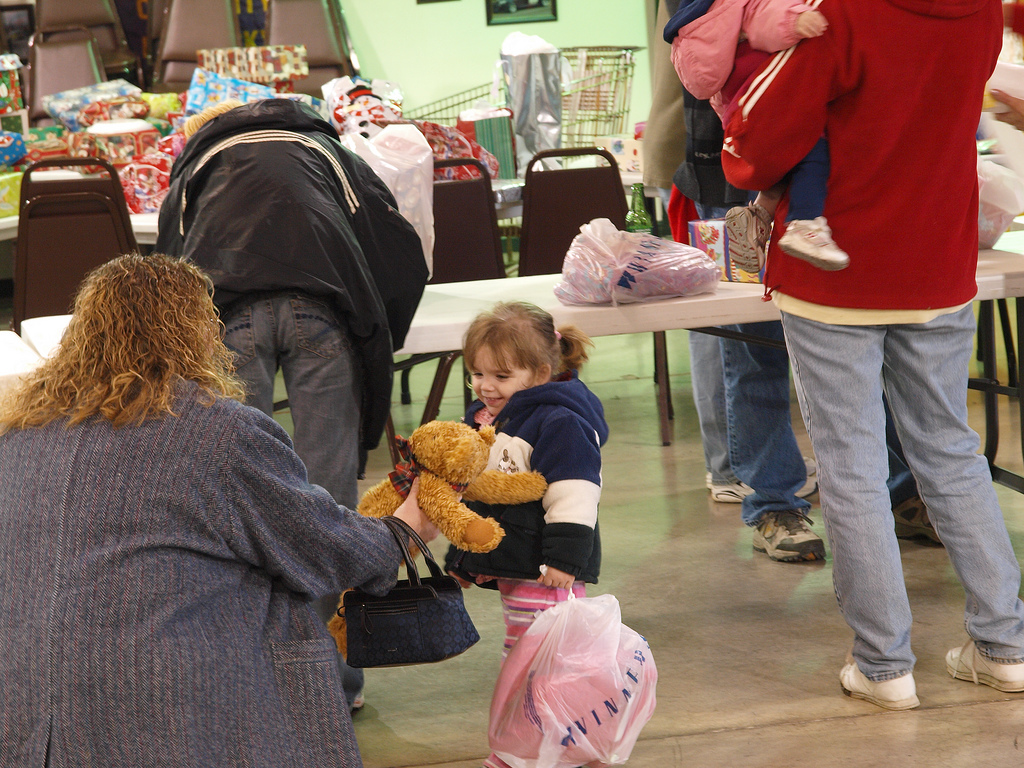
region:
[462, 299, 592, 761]
toddler in pigtails wearing a navy and white jacket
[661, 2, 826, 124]
baby in a pink coat with hood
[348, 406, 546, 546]
teddy bear with golden brown fur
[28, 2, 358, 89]
collection of brown stacking chairs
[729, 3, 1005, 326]
red fleece coat with white stripes on sleeve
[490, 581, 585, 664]
pink pants with white and blue stipes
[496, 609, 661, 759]
red objects in a white shopping bag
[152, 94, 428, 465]
black jacket with a light grey stripe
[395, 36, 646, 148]
a rolling store shopping basket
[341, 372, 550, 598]
a brown teddy bear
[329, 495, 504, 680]
a small black purse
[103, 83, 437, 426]
a black jacket with white stripes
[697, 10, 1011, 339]
a red jacket with white stripes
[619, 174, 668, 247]
a green bottle on the table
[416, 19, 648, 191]
a metal shopping cart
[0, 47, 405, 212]
a stack of presents on a table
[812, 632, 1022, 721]
white shoes on her feet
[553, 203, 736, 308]
shopping bag on the table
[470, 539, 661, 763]
girl holding a shopping bag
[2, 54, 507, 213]
presents on the table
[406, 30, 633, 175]
shopping cart next to the table with presents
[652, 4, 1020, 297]
person holding a baby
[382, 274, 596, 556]
girl looking at the teddy bear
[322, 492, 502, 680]
purse on the woman's arm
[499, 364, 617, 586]
girl has a white stripe on her coat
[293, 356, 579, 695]
a toy in the hand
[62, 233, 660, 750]
a woman holding a toy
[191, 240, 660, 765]
a teddy bear on the hand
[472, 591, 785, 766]
a pink bag on the ground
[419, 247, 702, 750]
a little girl standing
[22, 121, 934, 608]
chairs in the background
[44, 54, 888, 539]
brown chairs in the background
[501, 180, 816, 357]
plastic bag on the table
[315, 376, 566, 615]
woman holding a teddy bear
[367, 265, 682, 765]
girl holding a bag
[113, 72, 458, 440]
person is bending over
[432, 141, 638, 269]
a pair of chairs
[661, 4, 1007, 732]
woman holding a chair